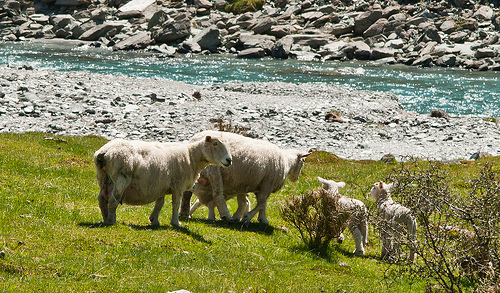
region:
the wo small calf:
[302, 163, 424, 262]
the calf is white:
[302, 157, 437, 242]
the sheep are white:
[50, 128, 334, 243]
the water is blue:
[174, 58, 271, 85]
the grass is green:
[9, 169, 75, 264]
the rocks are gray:
[55, 62, 232, 142]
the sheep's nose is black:
[220, 156, 236, 164]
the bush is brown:
[271, 189, 350, 250]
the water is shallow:
[108, 40, 305, 109]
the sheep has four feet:
[90, 164, 233, 259]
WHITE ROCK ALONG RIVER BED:
[29, 83, 105, 118]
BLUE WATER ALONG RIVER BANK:
[234, 68, 269, 93]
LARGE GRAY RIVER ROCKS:
[279, 21, 413, 59]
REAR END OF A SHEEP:
[91, 139, 134, 197]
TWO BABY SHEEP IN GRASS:
[314, 173, 416, 268]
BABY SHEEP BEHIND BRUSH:
[369, 179, 421, 266]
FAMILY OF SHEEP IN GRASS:
[77, 130, 430, 257]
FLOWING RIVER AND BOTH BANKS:
[41, 45, 498, 90]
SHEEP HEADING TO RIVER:
[68, 49, 318, 239]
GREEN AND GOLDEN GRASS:
[6, 142, 58, 189]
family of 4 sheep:
[71, 79, 431, 281]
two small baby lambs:
[291, 163, 426, 256]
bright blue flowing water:
[48, 25, 323, 121]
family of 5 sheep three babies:
[35, 69, 435, 279]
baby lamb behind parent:
[177, 164, 254, 221]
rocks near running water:
[146, 10, 459, 143]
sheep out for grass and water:
[61, 31, 423, 268]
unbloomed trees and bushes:
[350, 137, 485, 292]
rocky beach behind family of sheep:
[31, 61, 362, 209]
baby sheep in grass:
[310, 147, 421, 262]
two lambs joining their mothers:
[315, 168, 421, 269]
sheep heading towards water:
[67, 116, 422, 271]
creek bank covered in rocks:
[138, 11, 478, 123]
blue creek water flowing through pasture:
[50, 51, 296, 95]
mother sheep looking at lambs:
[195, 133, 239, 179]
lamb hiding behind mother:
[190, 189, 253, 226]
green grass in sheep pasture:
[7, 127, 107, 265]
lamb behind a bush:
[300, 174, 376, 255]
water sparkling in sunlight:
[289, 63, 439, 115]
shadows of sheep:
[62, 206, 282, 248]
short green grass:
[0, 131, 91, 221]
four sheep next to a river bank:
[80, 40, 426, 270]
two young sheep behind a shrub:
[296, 160, 426, 265]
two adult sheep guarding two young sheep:
[76, 95, 428, 277]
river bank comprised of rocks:
[0, 6, 495, 136]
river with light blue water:
[0, 30, 495, 130]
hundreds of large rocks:
[45, 0, 497, 65]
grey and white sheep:
[66, 110, 423, 265]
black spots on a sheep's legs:
[88, 127, 235, 238]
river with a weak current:
[1, 31, 496, 125]